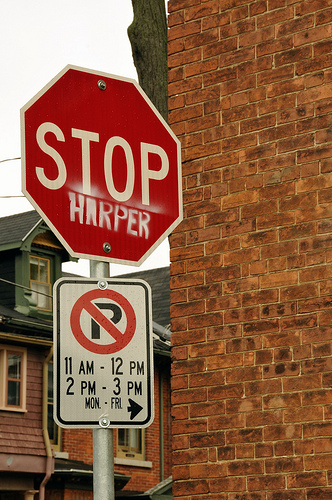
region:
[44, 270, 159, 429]
Parking sign on the pole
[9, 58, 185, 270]
Stop sign on a pole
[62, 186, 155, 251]
graffiti on a stop sign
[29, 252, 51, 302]
window for the attic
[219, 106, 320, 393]
brick face on a building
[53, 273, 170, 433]
No parking sign displaying times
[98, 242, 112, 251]
bolts on a stop sign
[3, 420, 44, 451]
shingles on the house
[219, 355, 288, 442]
red bricks on the building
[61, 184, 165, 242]
HARPER written on the stop sign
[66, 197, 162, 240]
white graffiti on stop sign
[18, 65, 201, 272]
red and white stop sign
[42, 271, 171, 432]
no parking sign with black lettering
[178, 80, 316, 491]
red brick building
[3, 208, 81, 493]
house with different colors on different levels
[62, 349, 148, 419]
hours of no parking indicated on sign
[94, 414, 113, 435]
silver screws attaching sign to pole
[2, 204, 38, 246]
black shingles on top of house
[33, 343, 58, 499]
drain pipe painted two different colors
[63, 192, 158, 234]
Harper spray painted on stop sign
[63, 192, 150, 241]
"Harper" sprayed painted on sign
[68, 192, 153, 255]
white spray paint on sign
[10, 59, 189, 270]
red and white sign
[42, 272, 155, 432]
black and white sign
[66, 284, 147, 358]
"P" crossed out on sign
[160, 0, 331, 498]
brown brick building next to sign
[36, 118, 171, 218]
"stop" in white lettering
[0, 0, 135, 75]
clear sky in the color white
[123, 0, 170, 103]
tree trunk sticking out of building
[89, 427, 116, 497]
silver pole holding signs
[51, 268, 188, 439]
a red white and black sign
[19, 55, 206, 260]
a red and white stop sign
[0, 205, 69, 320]
a green area on a house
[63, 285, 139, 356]
symbol indicating no parking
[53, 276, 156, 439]
a sign saying no parking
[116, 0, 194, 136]
a wood log above sign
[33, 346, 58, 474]
a yellow drain pipe on house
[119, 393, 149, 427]
a black arrow on sign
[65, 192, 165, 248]
painted name on sign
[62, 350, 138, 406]
black numbers on sign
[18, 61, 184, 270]
red and white stop sign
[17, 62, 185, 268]
stop sign with graffiti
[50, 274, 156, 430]
black and white no parking sign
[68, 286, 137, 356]
no parking symbol on sign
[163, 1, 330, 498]
red brick wall beside sign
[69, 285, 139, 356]
red and black no parking symbol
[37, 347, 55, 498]
downspout along edge of house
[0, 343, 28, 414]
second floor window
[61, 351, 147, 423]
times and days for no parking